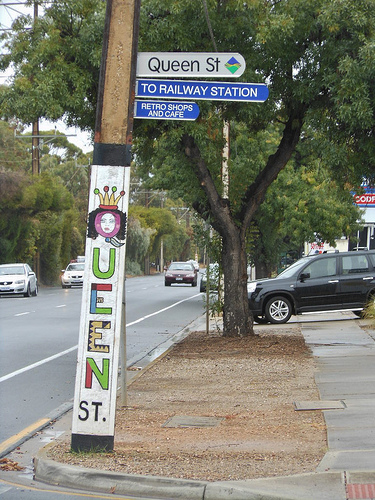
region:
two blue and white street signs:
[134, 75, 271, 123]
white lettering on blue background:
[131, 79, 259, 129]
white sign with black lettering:
[137, 47, 244, 75]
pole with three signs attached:
[73, 4, 124, 451]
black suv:
[227, 248, 373, 326]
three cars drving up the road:
[4, 249, 196, 298]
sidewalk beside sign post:
[295, 307, 374, 470]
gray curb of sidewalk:
[33, 452, 259, 498]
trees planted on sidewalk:
[150, 109, 325, 349]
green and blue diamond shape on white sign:
[223, 55, 242, 73]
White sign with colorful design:
[68, 174, 130, 429]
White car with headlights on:
[57, 262, 83, 287]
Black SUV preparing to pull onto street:
[250, 255, 372, 311]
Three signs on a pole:
[130, 46, 269, 121]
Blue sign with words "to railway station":
[137, 80, 268, 96]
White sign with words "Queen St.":
[144, 53, 244, 74]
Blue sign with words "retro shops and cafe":
[134, 103, 198, 120]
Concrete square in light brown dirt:
[159, 412, 226, 430]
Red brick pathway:
[344, 483, 373, 499]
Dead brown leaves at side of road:
[2, 452, 21, 476]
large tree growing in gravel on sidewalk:
[0, 0, 373, 339]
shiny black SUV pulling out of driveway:
[245, 249, 374, 325]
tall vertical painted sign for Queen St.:
[70, 138, 132, 454]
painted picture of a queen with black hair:
[87, 183, 129, 247]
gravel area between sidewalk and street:
[48, 327, 329, 481]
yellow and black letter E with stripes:
[85, 319, 111, 351]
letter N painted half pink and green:
[83, 356, 109, 389]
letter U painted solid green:
[91, 246, 118, 279]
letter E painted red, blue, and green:
[88, 282, 113, 314]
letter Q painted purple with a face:
[94, 210, 122, 237]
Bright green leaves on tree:
[338, 82, 355, 106]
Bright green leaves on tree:
[276, 207, 300, 224]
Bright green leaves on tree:
[317, 203, 343, 228]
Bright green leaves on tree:
[255, 222, 276, 254]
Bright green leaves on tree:
[276, 184, 296, 205]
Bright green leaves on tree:
[324, 54, 350, 86]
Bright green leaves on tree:
[16, 169, 41, 227]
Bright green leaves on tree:
[10, 89, 23, 100]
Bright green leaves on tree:
[29, 52, 56, 87]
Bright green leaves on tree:
[56, 59, 87, 95]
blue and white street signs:
[133, 80, 268, 129]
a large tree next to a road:
[179, 143, 285, 351]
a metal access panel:
[162, 408, 240, 450]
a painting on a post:
[74, 42, 142, 421]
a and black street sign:
[127, 49, 257, 77]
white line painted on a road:
[130, 285, 194, 332]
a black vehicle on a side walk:
[241, 232, 369, 328]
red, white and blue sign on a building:
[335, 184, 374, 219]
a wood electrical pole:
[20, 113, 46, 260]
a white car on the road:
[0, 253, 43, 308]